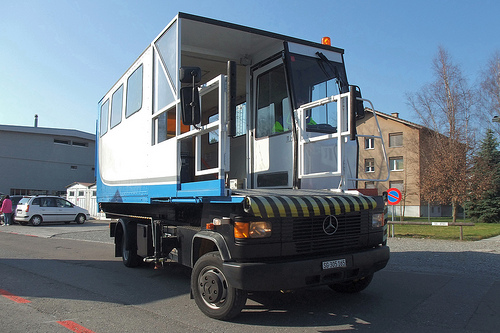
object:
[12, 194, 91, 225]
car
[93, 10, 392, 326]
truck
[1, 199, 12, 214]
coat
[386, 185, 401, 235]
sign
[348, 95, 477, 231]
building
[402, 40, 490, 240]
tree